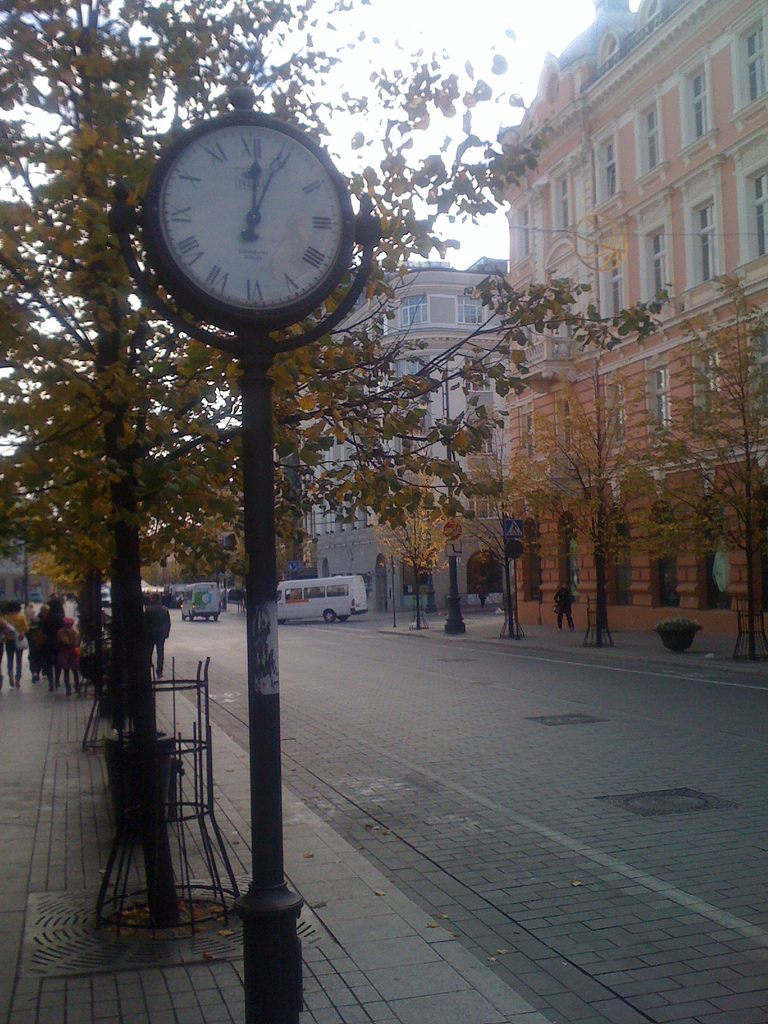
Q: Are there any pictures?
A: No, there are no pictures.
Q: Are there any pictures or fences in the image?
A: No, there are no pictures or fences.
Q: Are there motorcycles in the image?
A: No, there are no motorcycles.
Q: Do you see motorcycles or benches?
A: No, there are no motorcycles or benches.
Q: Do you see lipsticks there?
A: No, there are no lipsticks.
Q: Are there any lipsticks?
A: No, there are no lipsticks.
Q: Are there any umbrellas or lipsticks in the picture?
A: No, there are no lipsticks or umbrellas.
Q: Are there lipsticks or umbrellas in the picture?
A: No, there are no lipsticks or umbrellas.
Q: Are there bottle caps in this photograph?
A: No, there are no bottle caps.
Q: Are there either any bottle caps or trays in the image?
A: No, there are no bottle caps or trays.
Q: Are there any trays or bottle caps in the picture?
A: No, there are no bottle caps or trays.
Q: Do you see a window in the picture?
A: Yes, there is a window.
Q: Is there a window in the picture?
A: Yes, there is a window.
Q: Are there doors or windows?
A: Yes, there is a window.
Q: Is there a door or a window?
A: Yes, there is a window.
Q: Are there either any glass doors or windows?
A: Yes, there is a glass window.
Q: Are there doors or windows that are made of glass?
A: Yes, the window is made of glass.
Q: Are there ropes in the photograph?
A: No, there are no ropes.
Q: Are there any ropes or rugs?
A: No, there are no ropes or rugs.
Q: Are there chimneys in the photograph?
A: No, there are no chimneys.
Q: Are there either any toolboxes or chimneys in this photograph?
A: No, there are no chimneys or toolboxes.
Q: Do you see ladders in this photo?
A: No, there are no ladders.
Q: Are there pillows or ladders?
A: No, there are no ladders or pillows.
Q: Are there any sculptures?
A: No, there are no sculptures.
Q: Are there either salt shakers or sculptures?
A: No, there are no sculptures or salt shakers.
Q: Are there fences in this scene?
A: No, there are no fences.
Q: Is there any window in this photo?
A: Yes, there is a window.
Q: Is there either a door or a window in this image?
A: Yes, there is a window.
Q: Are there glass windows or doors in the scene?
A: Yes, there is a glass window.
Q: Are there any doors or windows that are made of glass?
A: Yes, the window is made of glass.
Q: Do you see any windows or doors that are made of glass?
A: Yes, the window is made of glass.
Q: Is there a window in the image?
A: Yes, there is a window.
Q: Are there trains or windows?
A: Yes, there is a window.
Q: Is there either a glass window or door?
A: Yes, there is a glass window.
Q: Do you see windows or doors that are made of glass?
A: Yes, the window is made of glass.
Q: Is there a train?
A: No, there are no trains.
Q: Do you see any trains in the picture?
A: No, there are no trains.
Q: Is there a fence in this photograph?
A: No, there are no fences.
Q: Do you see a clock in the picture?
A: Yes, there is a clock.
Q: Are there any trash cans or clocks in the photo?
A: Yes, there is a clock.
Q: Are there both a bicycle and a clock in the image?
A: No, there is a clock but no bicycles.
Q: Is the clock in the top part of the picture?
A: Yes, the clock is in the top of the image.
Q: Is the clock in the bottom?
A: No, the clock is in the top of the image.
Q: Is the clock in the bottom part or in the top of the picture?
A: The clock is in the top of the image.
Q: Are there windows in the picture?
A: Yes, there is a window.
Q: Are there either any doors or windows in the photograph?
A: Yes, there is a window.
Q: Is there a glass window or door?
A: Yes, there is a glass window.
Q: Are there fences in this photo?
A: No, there are no fences.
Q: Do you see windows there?
A: Yes, there is a window.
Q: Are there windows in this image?
A: Yes, there is a window.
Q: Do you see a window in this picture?
A: Yes, there is a window.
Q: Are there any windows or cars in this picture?
A: Yes, there is a window.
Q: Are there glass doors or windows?
A: Yes, there is a glass window.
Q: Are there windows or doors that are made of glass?
A: Yes, the window is made of glass.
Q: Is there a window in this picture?
A: Yes, there is a window.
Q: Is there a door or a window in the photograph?
A: Yes, there is a window.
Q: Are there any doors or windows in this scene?
A: Yes, there is a window.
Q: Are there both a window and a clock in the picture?
A: Yes, there are both a window and a clock.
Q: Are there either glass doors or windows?
A: Yes, there is a glass window.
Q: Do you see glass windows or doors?
A: Yes, there is a glass window.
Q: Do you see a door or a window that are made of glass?
A: Yes, the window is made of glass.